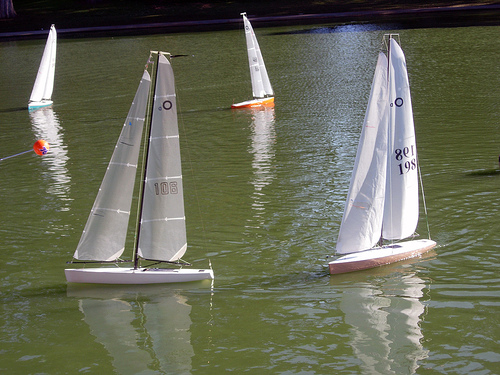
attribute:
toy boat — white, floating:
[65, 50, 214, 284]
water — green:
[0, 6, 499, 374]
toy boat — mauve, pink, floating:
[328, 33, 436, 276]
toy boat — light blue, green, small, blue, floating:
[29, 23, 57, 113]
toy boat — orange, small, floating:
[232, 12, 276, 113]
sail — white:
[74, 52, 188, 261]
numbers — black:
[395, 146, 416, 174]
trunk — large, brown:
[0, 1, 17, 20]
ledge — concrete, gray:
[1, 0, 499, 43]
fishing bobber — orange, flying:
[33, 139, 50, 155]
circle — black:
[162, 99, 172, 110]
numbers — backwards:
[394, 146, 415, 161]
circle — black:
[394, 97, 405, 108]